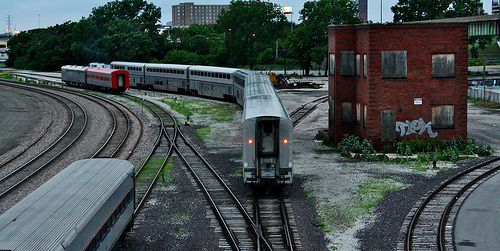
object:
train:
[97, 56, 300, 193]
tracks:
[3, 79, 78, 247]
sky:
[20, 0, 277, 30]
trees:
[214, 0, 292, 71]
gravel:
[362, 165, 406, 249]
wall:
[365, 75, 467, 148]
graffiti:
[392, 114, 435, 140]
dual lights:
[245, 137, 260, 146]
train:
[52, 64, 138, 95]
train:
[0, 154, 146, 232]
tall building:
[168, 3, 226, 26]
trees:
[10, 22, 53, 73]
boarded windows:
[379, 49, 412, 80]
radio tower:
[5, 12, 15, 33]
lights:
[280, 135, 296, 148]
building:
[326, 17, 469, 155]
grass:
[189, 103, 233, 121]